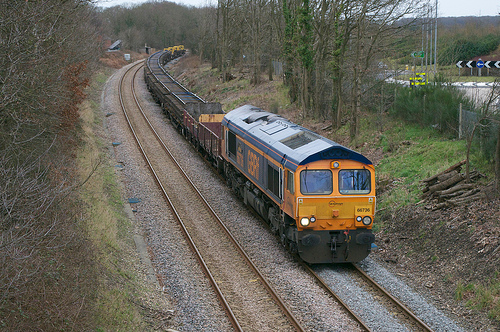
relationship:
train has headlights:
[144, 41, 375, 265] [299, 214, 377, 229]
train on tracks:
[144, 41, 375, 265] [121, 58, 433, 331]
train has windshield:
[144, 41, 375, 265] [299, 165, 373, 198]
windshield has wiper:
[299, 165, 373, 198] [303, 166, 316, 193]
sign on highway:
[413, 48, 431, 61] [381, 69, 499, 109]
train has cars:
[144, 41, 375, 265] [146, 52, 225, 167]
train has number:
[144, 41, 375, 265] [354, 205, 373, 218]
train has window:
[144, 41, 375, 265] [264, 166, 283, 196]